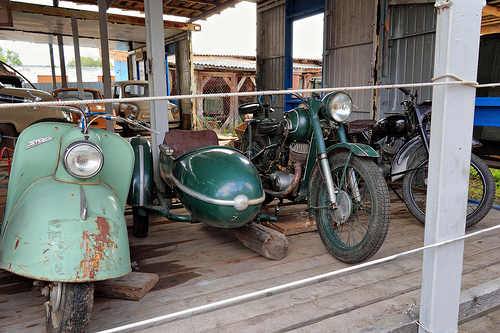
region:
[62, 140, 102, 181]
headlight on a moped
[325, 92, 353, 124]
headlight on a motorcycle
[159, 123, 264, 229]
a dark green sidecar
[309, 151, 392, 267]
wheel of a motorcycle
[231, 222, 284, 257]
a piece of wood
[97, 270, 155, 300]
a piece of wood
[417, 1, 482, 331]
a thin metal post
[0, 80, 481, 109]
a thin metal wire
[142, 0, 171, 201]
a white metal post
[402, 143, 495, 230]
wheel of a motorcycle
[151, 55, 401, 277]
Old motorcycle in a garage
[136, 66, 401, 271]
This motorcycle needs fixed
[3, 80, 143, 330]
Motorcycle with rust on it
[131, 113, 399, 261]
Two seater antique motorcycle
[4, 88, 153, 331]
Mint green antique scooter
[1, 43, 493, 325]
Antique motorcycle collection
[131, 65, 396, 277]
Motorcycle that has seen some miles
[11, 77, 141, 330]
Motorcycle in need of repair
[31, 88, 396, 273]
A collection of antique motorcycles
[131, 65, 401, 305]
This motorcycle has seen its glory days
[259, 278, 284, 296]
par tof a line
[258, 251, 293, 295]
par tof a line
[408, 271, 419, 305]
par tof a line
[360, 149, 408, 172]
part of a wheel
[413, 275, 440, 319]
edge of a whole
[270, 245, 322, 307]
part of a rrope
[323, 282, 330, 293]
part of a floor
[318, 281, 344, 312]
part of a floor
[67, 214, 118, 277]
rusty spot on green scooter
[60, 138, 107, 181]
chrome bezel around headlight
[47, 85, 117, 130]
orange car in the background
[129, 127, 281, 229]
green sidecar of motorcycle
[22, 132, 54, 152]
chrome nameplate on green scooter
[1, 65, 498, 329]
old transportations parked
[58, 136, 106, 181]
front light of scooter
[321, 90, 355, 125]
front light of scooter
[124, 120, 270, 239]
a sidecar of the tricycle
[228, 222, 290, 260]
a small log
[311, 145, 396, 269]
front wheel of the motorcycle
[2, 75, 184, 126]
old cars in the background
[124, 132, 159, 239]
a wheel of the sidecar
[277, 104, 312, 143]
a gas tank of the motorcycle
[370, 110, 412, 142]
a gas tank of the motorcycle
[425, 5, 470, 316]
Small white wooden beam on a building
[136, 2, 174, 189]
Small white wooden beam on a building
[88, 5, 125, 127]
Small white wooden beam on a building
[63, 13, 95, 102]
Small white wooden beam on a building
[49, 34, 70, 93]
Small white wooden beam on a building